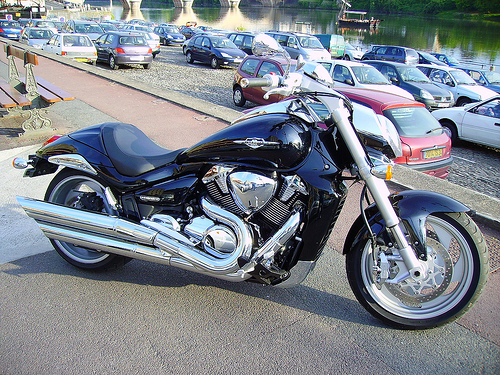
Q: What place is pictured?
A: It is a parking lot.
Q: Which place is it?
A: It is a parking lot.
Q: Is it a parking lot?
A: Yes, it is a parking lot.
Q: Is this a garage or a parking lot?
A: It is a parking lot.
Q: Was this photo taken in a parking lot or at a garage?
A: It was taken at a parking lot.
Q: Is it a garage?
A: No, it is a parking lot.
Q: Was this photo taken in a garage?
A: No, the picture was taken in a parking lot.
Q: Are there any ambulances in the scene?
A: No, there are no ambulances.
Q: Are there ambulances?
A: No, there are no ambulances.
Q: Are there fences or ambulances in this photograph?
A: No, there are no ambulances or fences.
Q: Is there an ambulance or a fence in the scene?
A: No, there are no ambulances or fences.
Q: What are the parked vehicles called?
A: The vehicles are cars.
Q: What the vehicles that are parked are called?
A: The vehicles are cars.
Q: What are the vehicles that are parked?
A: The vehicles are cars.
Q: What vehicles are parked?
A: The vehicles are cars.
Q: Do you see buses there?
A: No, there are no buses.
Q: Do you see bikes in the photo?
A: Yes, there is a bike.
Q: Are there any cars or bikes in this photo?
A: Yes, there is a bike.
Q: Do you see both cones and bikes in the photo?
A: No, there is a bike but no cones.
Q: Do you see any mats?
A: No, there are no mats.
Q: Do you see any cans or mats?
A: No, there are no mats or cans.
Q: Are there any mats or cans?
A: No, there are no mats or cans.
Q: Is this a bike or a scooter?
A: This is a bike.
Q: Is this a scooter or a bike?
A: This is a bike.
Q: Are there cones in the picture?
A: No, there are no cones.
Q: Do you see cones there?
A: No, there are no cones.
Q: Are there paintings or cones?
A: No, there are no cones or paintings.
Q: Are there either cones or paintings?
A: No, there are no cones or paintings.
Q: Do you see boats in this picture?
A: Yes, there is a boat.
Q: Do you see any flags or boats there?
A: Yes, there is a boat.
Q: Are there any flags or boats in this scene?
A: Yes, there is a boat.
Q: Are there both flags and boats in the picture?
A: No, there is a boat but no flags.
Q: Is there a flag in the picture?
A: No, there are no flags.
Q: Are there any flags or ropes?
A: No, there are no flags or ropes.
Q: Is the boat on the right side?
A: Yes, the boat is on the right of the image.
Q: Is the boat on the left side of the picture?
A: No, the boat is on the right of the image.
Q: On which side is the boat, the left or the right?
A: The boat is on the right of the image.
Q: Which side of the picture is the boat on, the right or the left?
A: The boat is on the right of the image.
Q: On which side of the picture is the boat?
A: The boat is on the right of the image.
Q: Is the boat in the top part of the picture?
A: Yes, the boat is in the top of the image.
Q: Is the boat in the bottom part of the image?
A: No, the boat is in the top of the image.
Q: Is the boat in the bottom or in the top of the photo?
A: The boat is in the top of the image.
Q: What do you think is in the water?
A: The boat is in the water.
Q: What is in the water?
A: The boat is in the water.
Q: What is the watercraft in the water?
A: The watercraft is a boat.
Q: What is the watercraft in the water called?
A: The watercraft is a boat.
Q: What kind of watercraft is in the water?
A: The watercraft is a boat.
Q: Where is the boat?
A: The boat is in the water.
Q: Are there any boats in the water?
A: Yes, there is a boat in the water.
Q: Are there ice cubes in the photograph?
A: No, there are no ice cubes.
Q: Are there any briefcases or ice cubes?
A: No, there are no ice cubes or briefcases.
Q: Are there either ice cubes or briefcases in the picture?
A: No, there are no ice cubes or briefcases.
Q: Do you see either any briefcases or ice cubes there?
A: No, there are no ice cubes or briefcases.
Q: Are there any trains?
A: No, there are no trains.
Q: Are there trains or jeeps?
A: No, there are no trains or jeeps.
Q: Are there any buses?
A: No, there are no buses.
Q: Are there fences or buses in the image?
A: No, there are no buses or fences.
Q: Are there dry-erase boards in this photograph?
A: No, there are no dry-erase boards.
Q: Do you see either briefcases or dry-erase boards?
A: No, there are no dry-erase boards or briefcases.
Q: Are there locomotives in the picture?
A: No, there are no locomotives.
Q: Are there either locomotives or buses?
A: No, there are no locomotives or buses.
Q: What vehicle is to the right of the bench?
A: The vehicle is a car.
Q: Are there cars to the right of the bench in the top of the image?
A: Yes, there is a car to the right of the bench.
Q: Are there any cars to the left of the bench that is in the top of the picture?
A: No, the car is to the right of the bench.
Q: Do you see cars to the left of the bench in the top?
A: No, the car is to the right of the bench.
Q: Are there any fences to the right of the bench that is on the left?
A: No, there is a car to the right of the bench.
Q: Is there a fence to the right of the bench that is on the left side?
A: No, there is a car to the right of the bench.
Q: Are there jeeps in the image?
A: No, there are no jeeps.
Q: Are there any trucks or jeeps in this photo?
A: No, there are no jeeps or trucks.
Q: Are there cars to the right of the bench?
A: Yes, there is a car to the right of the bench.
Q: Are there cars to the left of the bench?
A: No, the car is to the right of the bench.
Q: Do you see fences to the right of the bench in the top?
A: No, there is a car to the right of the bench.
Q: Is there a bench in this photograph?
A: Yes, there is a bench.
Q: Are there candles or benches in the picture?
A: Yes, there is a bench.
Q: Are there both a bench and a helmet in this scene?
A: No, there is a bench but no helmets.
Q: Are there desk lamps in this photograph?
A: No, there are no desk lamps.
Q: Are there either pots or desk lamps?
A: No, there are no desk lamps or pots.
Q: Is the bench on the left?
A: Yes, the bench is on the left of the image.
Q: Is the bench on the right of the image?
A: No, the bench is on the left of the image.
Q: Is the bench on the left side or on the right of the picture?
A: The bench is on the left of the image.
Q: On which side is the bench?
A: The bench is on the left of the image.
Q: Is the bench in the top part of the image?
A: Yes, the bench is in the top of the image.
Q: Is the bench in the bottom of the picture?
A: No, the bench is in the top of the image.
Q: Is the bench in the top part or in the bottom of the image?
A: The bench is in the top of the image.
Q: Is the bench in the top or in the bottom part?
A: The bench is in the top of the image.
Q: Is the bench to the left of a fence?
A: No, the bench is to the left of the car.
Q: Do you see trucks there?
A: No, there are no trucks.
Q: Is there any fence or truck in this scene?
A: No, there are no trucks or fences.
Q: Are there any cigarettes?
A: No, there are no cigarettes.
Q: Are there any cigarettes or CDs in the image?
A: No, there are no cigarettes or cds.